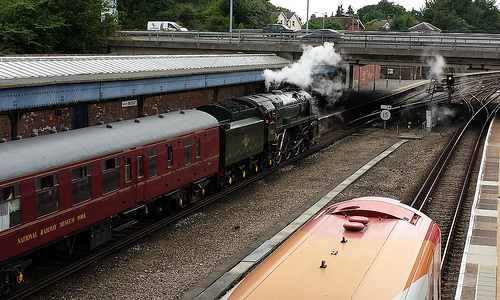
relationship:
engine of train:
[237, 83, 338, 167] [130, 102, 295, 191]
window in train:
[164, 141, 176, 171] [0, 86, 321, 285]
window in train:
[120, 155, 134, 184] [0, 86, 321, 285]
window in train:
[134, 150, 147, 180] [0, 86, 321, 285]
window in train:
[30, 169, 62, 221] [0, 86, 321, 285]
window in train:
[192, 135, 203, 160] [0, 86, 321, 285]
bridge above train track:
[97, 25, 499, 72] [9, 69, 497, 294]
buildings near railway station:
[292, 0, 380, 30] [3, 37, 493, 297]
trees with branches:
[0, 2, 280, 49] [4, 0, 277, 47]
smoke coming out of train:
[257, 41, 344, 101] [212, 90, 321, 182]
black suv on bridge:
[265, 24, 296, 31] [115, 27, 499, 55]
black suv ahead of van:
[265, 24, 296, 31] [146, 20, 189, 32]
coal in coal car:
[218, 96, 253, 112] [195, 94, 267, 169]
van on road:
[145, 18, 187, 33] [113, 30, 499, 48]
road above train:
[113, 30, 499, 48] [0, 86, 321, 285]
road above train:
[113, 30, 499, 48] [215, 194, 450, 297]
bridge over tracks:
[105, 28, 500, 60] [183, 70, 498, 297]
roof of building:
[1, 48, 289, 85] [3, 52, 302, 144]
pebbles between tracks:
[77, 124, 397, 298] [0, 72, 498, 296]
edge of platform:
[453, 100, 498, 296] [488, 121, 497, 296]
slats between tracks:
[408, 113, 485, 245] [384, 81, 496, 298]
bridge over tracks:
[105, 28, 500, 60] [241, 66, 492, 298]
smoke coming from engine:
[260, 40, 350, 107] [237, 77, 320, 164]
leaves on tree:
[39, 20, 62, 32] [4, 1, 126, 56]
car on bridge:
[296, 27, 345, 38] [97, 22, 484, 63]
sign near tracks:
[373, 103, 391, 126] [319, 63, 499, 145]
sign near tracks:
[373, 103, 391, 126] [397, 83, 499, 298]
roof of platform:
[0, 53, 294, 85] [0, 48, 298, 167]